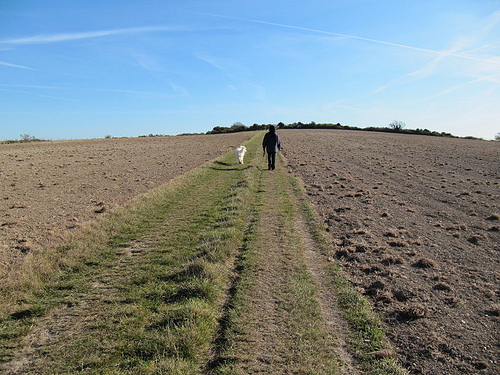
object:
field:
[0, 132, 260, 287]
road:
[0, 132, 374, 375]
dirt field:
[278, 129, 500, 337]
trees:
[253, 123, 258, 128]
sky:
[2, 4, 499, 126]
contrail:
[249, 20, 499, 64]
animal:
[235, 146, 246, 165]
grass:
[0, 128, 500, 375]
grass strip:
[0, 132, 500, 374]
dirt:
[0, 127, 500, 365]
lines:
[183, 6, 500, 65]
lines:
[372, 14, 500, 94]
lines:
[2, 24, 231, 45]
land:
[0, 129, 500, 351]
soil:
[24, 151, 144, 201]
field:
[0, 127, 404, 375]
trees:
[276, 121, 286, 128]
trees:
[20, 132, 30, 142]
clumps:
[277, 130, 499, 374]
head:
[269, 125, 276, 132]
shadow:
[213, 160, 232, 166]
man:
[262, 125, 282, 170]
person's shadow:
[201, 165, 259, 171]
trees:
[105, 134, 111, 138]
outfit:
[262, 131, 281, 170]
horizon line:
[28, 105, 481, 131]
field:
[279, 127, 500, 375]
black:
[268, 153, 277, 170]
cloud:
[1, 0, 500, 138]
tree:
[231, 121, 248, 131]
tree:
[388, 120, 406, 132]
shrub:
[206, 131, 211, 135]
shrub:
[342, 125, 351, 130]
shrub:
[351, 126, 362, 130]